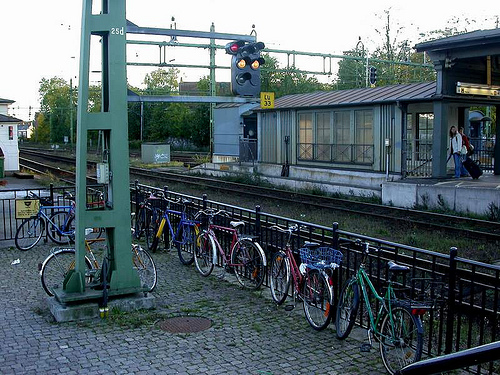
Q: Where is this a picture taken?
A: Train station.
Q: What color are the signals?
A: Red and yellow.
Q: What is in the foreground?
A: Bikes.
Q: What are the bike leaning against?
A: A fence.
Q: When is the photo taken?
A: Daytime.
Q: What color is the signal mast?
A: Green.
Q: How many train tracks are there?
A: Two sets.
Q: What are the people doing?
A: Waiting for the train.